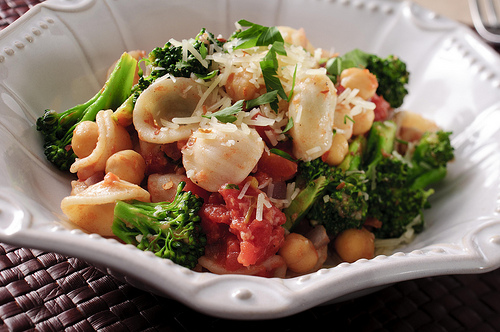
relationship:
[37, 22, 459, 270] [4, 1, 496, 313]
food in bowl